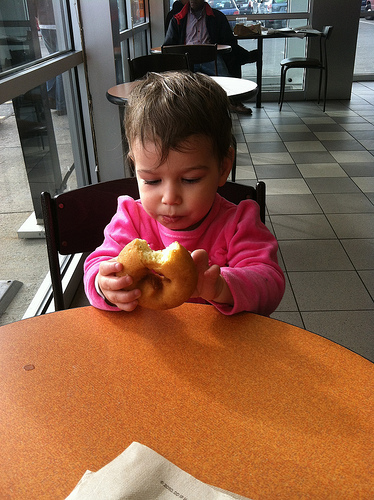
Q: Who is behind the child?
A: A man.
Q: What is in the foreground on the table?
A: Papers.